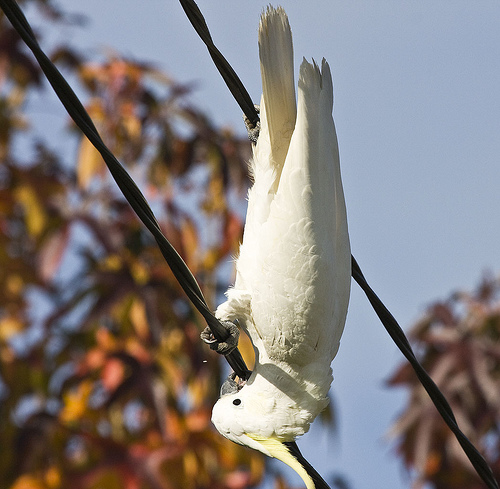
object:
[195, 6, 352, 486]
bird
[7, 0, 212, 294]
wire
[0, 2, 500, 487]
sky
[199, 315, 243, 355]
claw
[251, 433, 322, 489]
feather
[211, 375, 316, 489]
head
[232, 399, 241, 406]
eye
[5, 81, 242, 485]
tree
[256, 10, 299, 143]
tail feathers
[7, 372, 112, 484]
leaves